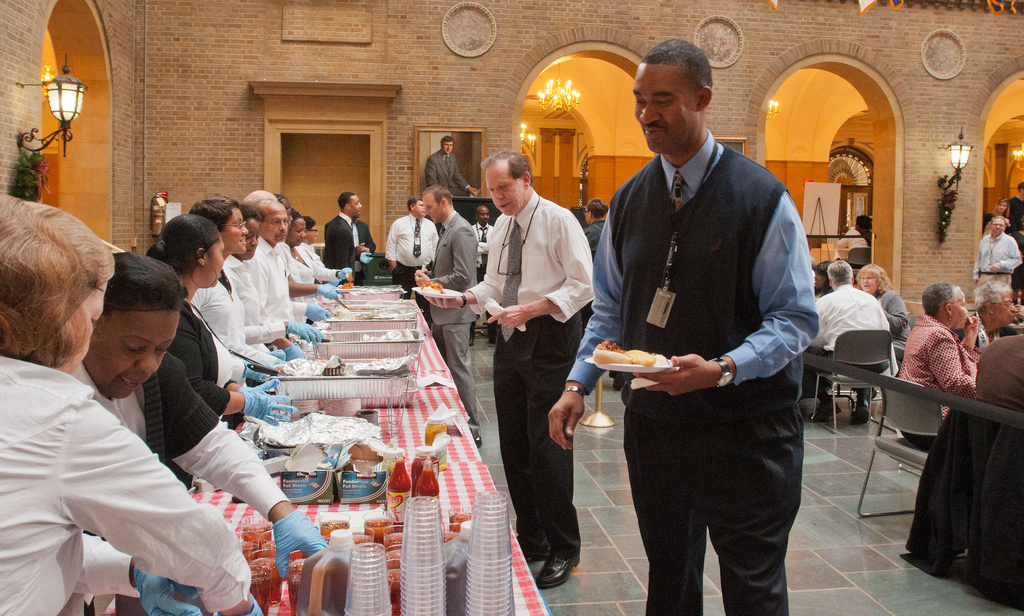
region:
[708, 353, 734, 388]
Watch on the wrist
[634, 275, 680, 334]
Identification badge on the man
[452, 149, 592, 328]
Man wearing a tie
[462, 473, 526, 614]
Stack of clear plastic cups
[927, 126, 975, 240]
Light on the wall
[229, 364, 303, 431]
Blue glove on the hand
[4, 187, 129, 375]
Hair net on the head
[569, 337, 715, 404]
Plate of food in the hand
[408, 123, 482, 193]
Picture on the wall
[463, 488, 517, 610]
cups are stacked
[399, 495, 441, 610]
cups are clear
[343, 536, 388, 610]
cups are stacked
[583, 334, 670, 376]
food is on top of plate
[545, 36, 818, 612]
man is standing in front of table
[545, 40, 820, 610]
man is holding a plate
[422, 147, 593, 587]
man is standing in front of the table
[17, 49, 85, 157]
light fixture is attached to wall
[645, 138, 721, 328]
name badge is around guys neck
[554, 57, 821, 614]
The man in a blue vest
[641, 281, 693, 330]
The card around the mans neck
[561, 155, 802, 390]
The blue long sleeved shirt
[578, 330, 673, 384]
The plate of food in the african american man's hand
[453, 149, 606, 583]
The man with a tan shirt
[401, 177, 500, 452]
A brown haired man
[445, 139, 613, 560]
The man withe black shoes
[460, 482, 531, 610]
The stack of plastic cups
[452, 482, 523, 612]
a stack of plastic cups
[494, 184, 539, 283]
a man with a pair of glasses around his neck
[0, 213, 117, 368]
a woman wearing a hair net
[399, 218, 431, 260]
a man wearing a tie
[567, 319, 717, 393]
a man holding a plate of food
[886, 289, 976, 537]
a woman sitting in a chair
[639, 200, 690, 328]
a man with a name badge around his neck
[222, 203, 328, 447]
a line of people wearing white shirts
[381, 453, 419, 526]
a clear bottle of hot sauce on a table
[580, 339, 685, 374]
plate has food on it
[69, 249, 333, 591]
woman is reaching onto the table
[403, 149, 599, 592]
man is holding a plate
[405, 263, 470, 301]
food is on the plate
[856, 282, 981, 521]
woman is sitting in a chair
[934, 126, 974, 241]
illuminated light is mounted to the wall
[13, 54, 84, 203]
illuminated light is mounted to the wall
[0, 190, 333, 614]
women are helping each other